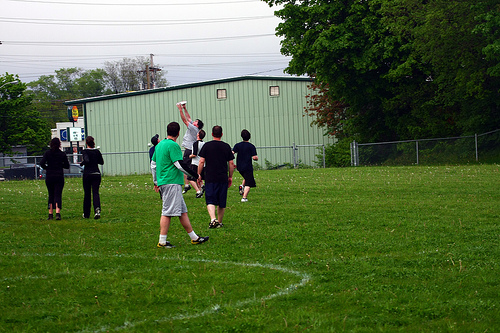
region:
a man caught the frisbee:
[166, 95, 220, 171]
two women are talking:
[34, 112, 146, 283]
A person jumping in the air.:
[175, 97, 202, 198]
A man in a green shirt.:
[150, 120, 210, 246]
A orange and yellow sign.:
[65, 102, 82, 162]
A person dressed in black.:
[37, 135, 72, 220]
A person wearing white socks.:
[148, 120, 209, 247]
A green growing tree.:
[260, 0, 496, 165]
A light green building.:
[58, 73, 363, 174]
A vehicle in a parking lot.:
[33, 157, 83, 180]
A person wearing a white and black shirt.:
[186, 126, 206, 197]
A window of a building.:
[268, 84, 281, 97]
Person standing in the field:
[229, 124, 270, 233]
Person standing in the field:
[200, 119, 230, 243]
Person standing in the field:
[149, 117, 197, 260]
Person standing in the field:
[145, 129, 162, 186]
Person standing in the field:
[72, 134, 115, 214]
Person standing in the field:
[35, 122, 72, 224]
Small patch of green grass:
[425, 272, 474, 327]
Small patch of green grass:
[351, 267, 388, 327]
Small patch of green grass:
[225, 242, 338, 328]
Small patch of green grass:
[117, 259, 185, 328]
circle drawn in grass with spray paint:
[1, 246, 310, 331]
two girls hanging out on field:
[37, 134, 106, 220]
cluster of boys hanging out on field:
[141, 98, 264, 249]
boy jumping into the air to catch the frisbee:
[174, 96, 206, 198]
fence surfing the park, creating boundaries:
[1, 129, 498, 176]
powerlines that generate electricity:
[0, 0, 302, 75]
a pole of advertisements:
[64, 105, 85, 170]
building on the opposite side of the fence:
[65, 74, 369, 190]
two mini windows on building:
[212, 81, 288, 100]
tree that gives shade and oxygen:
[253, 1, 495, 168]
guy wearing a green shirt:
[152, 122, 208, 248]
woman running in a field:
[81, 135, 103, 218]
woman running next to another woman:
[41, 137, 68, 219]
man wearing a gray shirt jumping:
[178, 101, 203, 191]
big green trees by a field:
[261, 0, 498, 167]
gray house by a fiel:
[66, 74, 336, 176]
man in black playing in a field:
[233, 129, 258, 201]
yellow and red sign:
[66, 104, 78, 121]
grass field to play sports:
[0, 165, 499, 332]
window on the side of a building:
[269, 85, 279, 95]